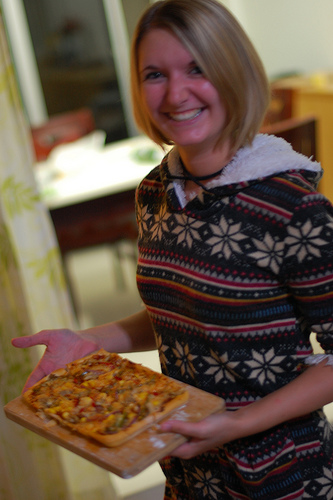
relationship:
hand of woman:
[22, 332, 111, 385] [90, 37, 306, 380]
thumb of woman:
[3, 329, 32, 358] [90, 37, 306, 380]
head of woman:
[131, 6, 253, 142] [90, 37, 306, 380]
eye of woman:
[135, 70, 169, 99] [90, 37, 306, 380]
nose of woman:
[156, 73, 194, 101] [90, 37, 306, 380]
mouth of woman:
[154, 110, 216, 130] [90, 37, 306, 380]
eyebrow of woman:
[139, 63, 166, 75] [90, 37, 306, 380]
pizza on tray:
[60, 361, 166, 424] [14, 338, 215, 496]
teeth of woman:
[174, 113, 190, 121] [90, 37, 306, 380]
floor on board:
[141, 423, 175, 457] [18, 346, 192, 497]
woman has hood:
[90, 37, 306, 380] [234, 122, 333, 206]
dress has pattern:
[126, 177, 332, 370] [179, 216, 286, 266]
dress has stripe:
[126, 177, 332, 370] [232, 199, 315, 220]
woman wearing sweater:
[90, 37, 306, 380] [159, 194, 326, 342]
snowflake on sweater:
[194, 214, 265, 280] [159, 194, 326, 342]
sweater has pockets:
[159, 194, 326, 342] [234, 450, 317, 489]